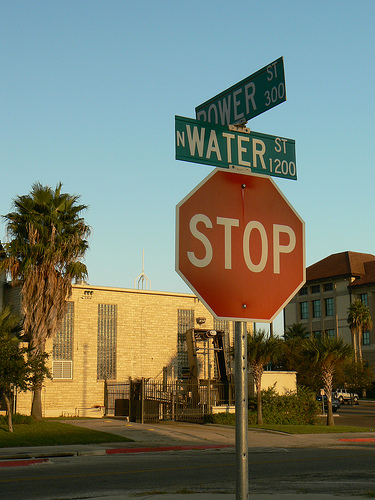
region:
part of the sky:
[91, 147, 145, 207]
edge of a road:
[87, 449, 153, 460]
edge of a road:
[152, 436, 175, 462]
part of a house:
[21, 386, 56, 428]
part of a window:
[37, 275, 74, 382]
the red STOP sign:
[168, 163, 307, 326]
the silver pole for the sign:
[228, 320, 246, 498]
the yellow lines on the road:
[70, 454, 207, 479]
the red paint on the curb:
[102, 432, 230, 461]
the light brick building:
[122, 295, 171, 365]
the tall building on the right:
[278, 230, 374, 403]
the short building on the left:
[12, 263, 283, 434]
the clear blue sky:
[2, 45, 132, 161]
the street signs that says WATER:
[171, 109, 303, 175]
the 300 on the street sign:
[261, 84, 285, 101]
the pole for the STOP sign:
[229, 321, 256, 498]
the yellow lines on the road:
[98, 462, 179, 475]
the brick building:
[121, 296, 169, 368]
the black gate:
[124, 373, 213, 429]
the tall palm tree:
[2, 175, 89, 420]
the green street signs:
[163, 69, 300, 177]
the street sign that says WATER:
[168, 111, 298, 175]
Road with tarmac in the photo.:
[87, 464, 163, 481]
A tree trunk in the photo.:
[29, 391, 46, 416]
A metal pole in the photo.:
[232, 410, 255, 484]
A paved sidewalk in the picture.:
[46, 441, 77, 451]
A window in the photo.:
[52, 362, 71, 380]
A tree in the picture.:
[319, 350, 340, 420]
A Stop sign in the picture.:
[185, 217, 304, 318]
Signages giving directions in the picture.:
[180, 54, 302, 172]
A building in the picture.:
[122, 300, 168, 372]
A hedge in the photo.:
[273, 393, 314, 424]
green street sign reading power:
[177, 46, 295, 134]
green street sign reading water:
[169, 108, 304, 185]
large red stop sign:
[158, 151, 321, 331]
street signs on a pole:
[152, 43, 335, 490]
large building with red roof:
[267, 229, 373, 411]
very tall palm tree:
[1, 174, 97, 441]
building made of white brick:
[2, 255, 257, 441]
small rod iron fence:
[102, 364, 254, 430]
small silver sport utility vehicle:
[326, 378, 368, 411]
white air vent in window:
[40, 286, 84, 389]